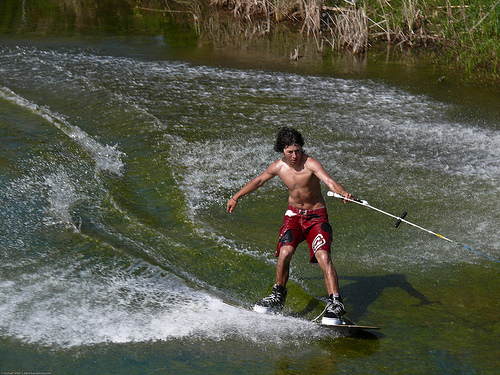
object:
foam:
[172, 325, 178, 332]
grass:
[443, 16, 500, 80]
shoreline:
[169, 0, 500, 83]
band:
[231, 196, 238, 202]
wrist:
[231, 194, 240, 202]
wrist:
[338, 189, 347, 195]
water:
[0, 0, 495, 375]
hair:
[273, 126, 306, 154]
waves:
[4, 168, 343, 353]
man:
[222, 127, 350, 318]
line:
[341, 198, 500, 264]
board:
[249, 305, 381, 330]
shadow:
[283, 271, 434, 339]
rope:
[327, 192, 500, 264]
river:
[0, 0, 500, 375]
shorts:
[275, 204, 334, 264]